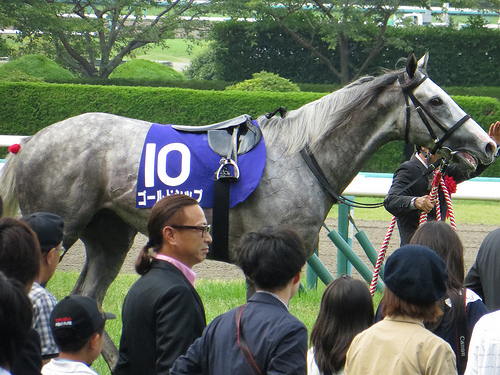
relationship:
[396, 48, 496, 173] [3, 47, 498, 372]
head of horse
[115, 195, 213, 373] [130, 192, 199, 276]
man with brown hair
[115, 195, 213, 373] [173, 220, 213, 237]
man with glasses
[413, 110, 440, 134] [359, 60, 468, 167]
halter on horse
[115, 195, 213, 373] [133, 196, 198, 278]
man with brown hair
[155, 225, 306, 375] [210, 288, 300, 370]
man wearing a suit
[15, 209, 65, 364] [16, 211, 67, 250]
person wearing a beret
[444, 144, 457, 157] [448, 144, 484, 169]
bit in mouth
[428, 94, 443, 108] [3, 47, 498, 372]
eye on horse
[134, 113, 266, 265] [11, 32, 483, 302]
harness on horse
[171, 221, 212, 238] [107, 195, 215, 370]
eye glasses on man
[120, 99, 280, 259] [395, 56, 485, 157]
harness on face